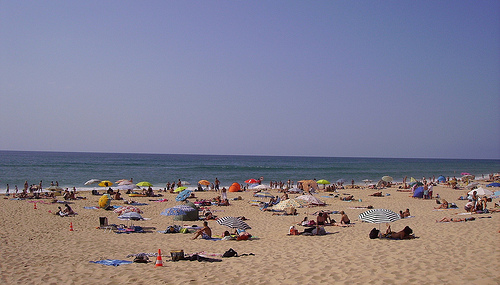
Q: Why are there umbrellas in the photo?
A: To provide shade.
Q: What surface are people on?
A: Sand.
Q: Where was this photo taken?
A: At the beach.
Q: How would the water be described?
A: Dark blue and calm.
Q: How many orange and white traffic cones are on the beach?
A: Three.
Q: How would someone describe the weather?
A: Sunny with clear skies.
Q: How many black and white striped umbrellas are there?
A: Two.